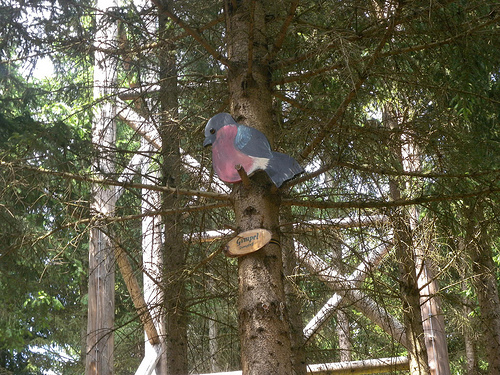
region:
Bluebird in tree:
[192, 111, 309, 196]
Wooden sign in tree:
[207, 224, 284, 261]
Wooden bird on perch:
[184, 103, 311, 205]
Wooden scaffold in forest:
[82, 59, 444, 323]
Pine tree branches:
[20, 109, 183, 204]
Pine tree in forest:
[163, 50, 344, 366]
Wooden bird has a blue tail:
[262, 150, 311, 192]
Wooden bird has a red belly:
[207, 141, 251, 186]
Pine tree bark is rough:
[227, 273, 304, 368]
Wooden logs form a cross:
[286, 226, 416, 360]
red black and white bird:
[187, 114, 327, 206]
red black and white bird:
[174, 104, 279, 170]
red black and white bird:
[188, 80, 359, 256]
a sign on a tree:
[183, 217, 299, 262]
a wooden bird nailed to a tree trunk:
[184, 111, 334, 201]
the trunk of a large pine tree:
[202, 23, 318, 362]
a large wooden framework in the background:
[87, 11, 468, 362]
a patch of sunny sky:
[14, 11, 66, 76]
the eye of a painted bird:
[204, 123, 220, 137]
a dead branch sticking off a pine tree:
[26, 160, 216, 234]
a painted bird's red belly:
[212, 138, 247, 172]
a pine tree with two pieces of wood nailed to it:
[201, 64, 303, 356]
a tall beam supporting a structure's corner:
[95, 54, 125, 367]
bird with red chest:
[193, 105, 316, 202]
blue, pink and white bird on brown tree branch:
[196, 94, 306, 199]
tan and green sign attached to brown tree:
[218, 222, 284, 263]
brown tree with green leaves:
[13, 10, 146, 197]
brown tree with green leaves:
[1, 217, 182, 373]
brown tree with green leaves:
[76, 5, 368, 99]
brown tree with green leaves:
[348, 16, 492, 224]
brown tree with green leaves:
[318, 196, 470, 362]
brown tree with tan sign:
[215, 219, 305, 367]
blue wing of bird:
[227, 117, 277, 163]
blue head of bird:
[200, 112, 235, 148]